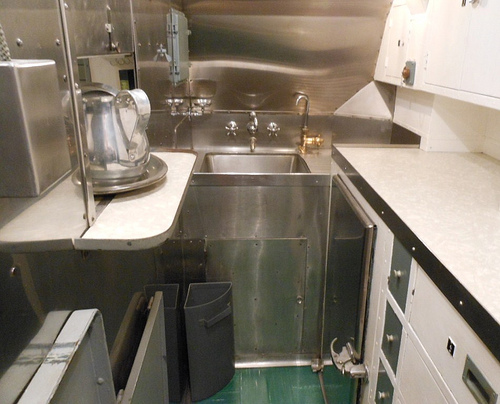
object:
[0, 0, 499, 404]
kitchen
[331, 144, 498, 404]
counter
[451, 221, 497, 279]
table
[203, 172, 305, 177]
edge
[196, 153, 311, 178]
sink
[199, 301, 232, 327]
handle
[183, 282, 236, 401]
bin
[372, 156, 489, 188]
countertop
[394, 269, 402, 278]
drawer pull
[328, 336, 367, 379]
handle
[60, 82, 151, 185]
kettle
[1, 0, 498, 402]
kitchen area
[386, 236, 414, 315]
drawer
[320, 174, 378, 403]
refrigerator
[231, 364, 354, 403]
floor